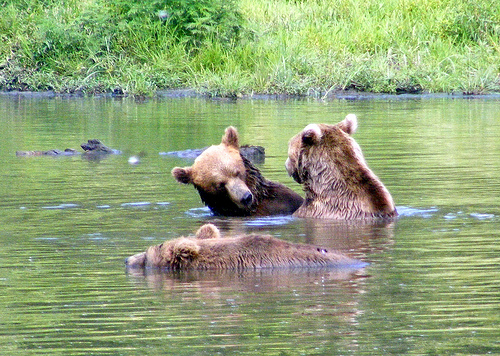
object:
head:
[285, 114, 366, 184]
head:
[124, 224, 220, 269]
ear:
[220, 126, 239, 149]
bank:
[146, 43, 446, 104]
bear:
[285, 114, 399, 219]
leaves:
[105, 0, 252, 46]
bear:
[124, 223, 367, 268]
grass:
[0, 0, 499, 97]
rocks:
[16, 139, 265, 164]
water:
[0, 96, 499, 356]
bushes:
[31, 42, 98, 75]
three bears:
[124, 114, 398, 270]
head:
[171, 126, 264, 216]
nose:
[240, 190, 252, 207]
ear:
[301, 124, 322, 148]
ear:
[335, 114, 358, 135]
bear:
[171, 126, 304, 217]